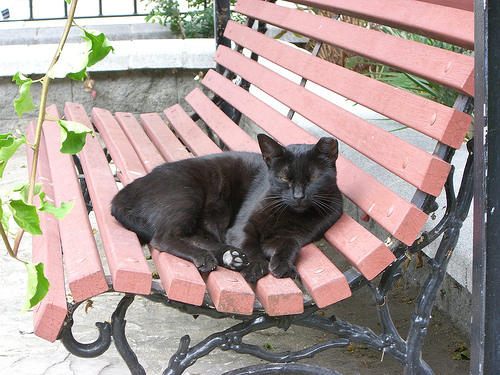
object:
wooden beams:
[33, 0, 500, 375]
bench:
[31, 0, 500, 375]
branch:
[0, 0, 114, 310]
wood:
[51, 107, 151, 289]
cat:
[109, 133, 346, 286]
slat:
[41, 102, 109, 301]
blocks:
[3, 45, 198, 114]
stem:
[15, 1, 117, 127]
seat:
[30, 0, 489, 344]